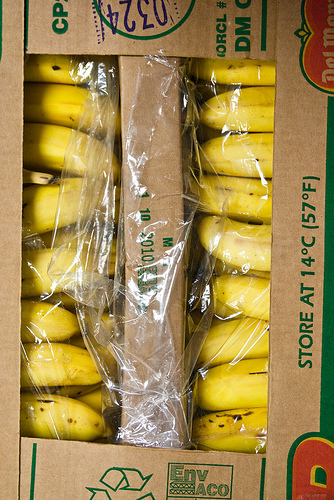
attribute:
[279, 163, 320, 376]
instructions — green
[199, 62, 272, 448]
bananas — yellow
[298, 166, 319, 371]
lettering — green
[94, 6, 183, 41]
circle — green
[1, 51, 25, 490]
box — cardboard 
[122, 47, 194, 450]
box — cardboard 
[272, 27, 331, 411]
box — cardboard 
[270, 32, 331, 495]
box — cardboard 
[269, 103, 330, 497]
box — cardboard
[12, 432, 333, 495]
box — cardboard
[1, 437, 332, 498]
box — cardboard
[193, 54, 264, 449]
bananas — yellow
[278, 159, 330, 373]
storage instructions — green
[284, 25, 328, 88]
logo — red, white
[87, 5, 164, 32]
numbers — blue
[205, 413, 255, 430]
spot — brown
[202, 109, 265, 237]
flesh — yellow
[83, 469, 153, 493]
sign — green, recycle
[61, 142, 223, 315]
bananas — yellow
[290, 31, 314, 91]
logo — red, white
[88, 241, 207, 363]
wrap — plastic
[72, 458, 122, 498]
symbol — recycle, green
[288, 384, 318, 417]
box — light, brown